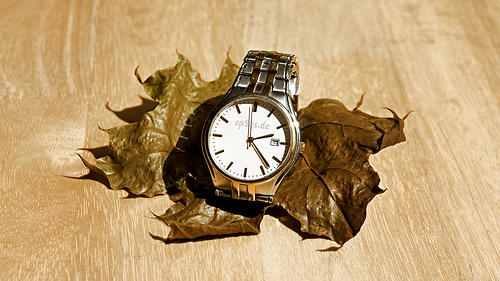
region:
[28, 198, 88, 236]
this is the table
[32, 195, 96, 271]
the table is wooden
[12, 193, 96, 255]
the table is brown in color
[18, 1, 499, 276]
the table is big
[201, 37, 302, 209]
this is a wrist watch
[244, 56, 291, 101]
the watch is grey in color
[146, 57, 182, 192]
this is a leaf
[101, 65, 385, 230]
the leaf is big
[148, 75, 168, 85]
the leaf is green in color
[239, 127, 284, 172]
twenty three minutes past two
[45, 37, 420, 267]
a watch, inexplicably on a leaf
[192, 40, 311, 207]
a silvertone watch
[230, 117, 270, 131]
a german watchmaker's website [unclear name, domain is 'de']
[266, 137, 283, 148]
little box for the date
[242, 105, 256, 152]
the second hand & its shadow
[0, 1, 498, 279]
probably another class assignment, sent to greyscale & then sepiatoned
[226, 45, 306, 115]
expanding silvertone metal watchband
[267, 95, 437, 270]
a crinkly leaf & its close shadow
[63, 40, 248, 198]
another crinkly leaf & its close shadow, this one greener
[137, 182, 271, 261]
either the place where the leaves cross & the shadow therefrom, or another leaf & ditto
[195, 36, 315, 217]
silver watch on table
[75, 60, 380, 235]
brown leaves behind watch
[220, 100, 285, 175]
hash marks on face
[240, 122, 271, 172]
three hands on watch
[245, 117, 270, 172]
black hands on watch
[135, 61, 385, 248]
crumpled dead leaves behind watch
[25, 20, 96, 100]
brown and wooden platform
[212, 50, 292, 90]
silver band on watch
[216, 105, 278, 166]
white face on watch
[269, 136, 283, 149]
small opening on watch for date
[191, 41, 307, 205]
silver watch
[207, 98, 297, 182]
black and white face of the clock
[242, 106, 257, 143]
skinny clock hand that indicates the seconds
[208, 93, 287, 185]
black marks around the circumference of the clock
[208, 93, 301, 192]
watch indicating it's about 2:24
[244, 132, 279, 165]
two clock hands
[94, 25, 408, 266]
watch sitting on a leaf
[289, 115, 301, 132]
glare on the side of the watch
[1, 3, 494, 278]
leaf sitting on a light brown surface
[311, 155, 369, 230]
vein of the leaf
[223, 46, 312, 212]
Wristwatch sitting on leaf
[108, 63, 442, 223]
Green leaf on wood table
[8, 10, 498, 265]
Wood surface under objects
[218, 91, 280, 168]
Glass face of wrist watch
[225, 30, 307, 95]
Metal band of wrist watch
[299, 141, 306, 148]
Small winder of wrist watch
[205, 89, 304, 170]
White clock face on watch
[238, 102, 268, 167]
Small arms of wrist watch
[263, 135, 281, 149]
Calender window on watch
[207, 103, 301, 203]
Gold frame of wrist watch